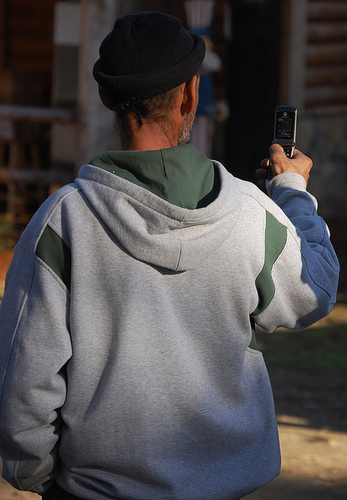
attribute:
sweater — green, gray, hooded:
[1, 142, 339, 497]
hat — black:
[91, 11, 204, 102]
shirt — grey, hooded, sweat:
[4, 149, 335, 498]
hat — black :
[91, 4, 206, 109]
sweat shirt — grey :
[0, 143, 340, 498]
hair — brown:
[101, 69, 180, 136]